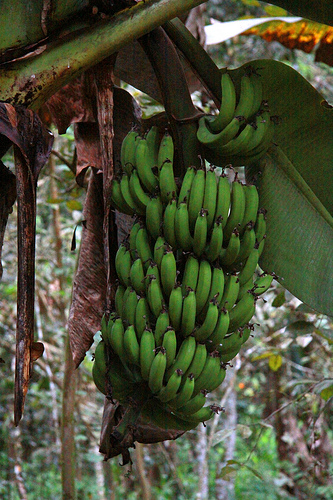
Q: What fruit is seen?
A: Banana.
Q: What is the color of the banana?
A: Green.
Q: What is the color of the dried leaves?
A: Brown.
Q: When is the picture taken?
A: Daytime.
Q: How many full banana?
A: 1.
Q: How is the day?
A: Sunny.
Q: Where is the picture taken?
A: In the jungle.